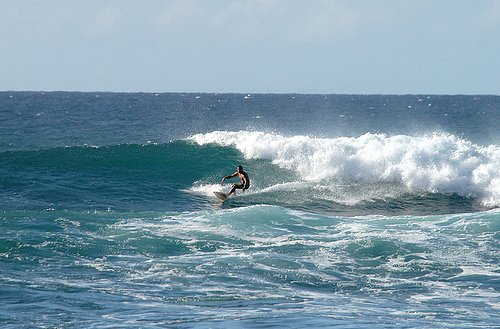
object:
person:
[222, 165, 251, 196]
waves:
[0, 126, 500, 323]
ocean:
[0, 90, 500, 329]